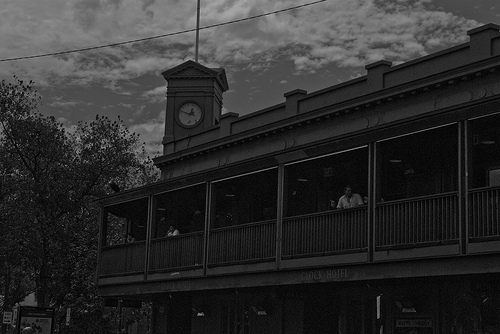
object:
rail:
[103, 240, 145, 250]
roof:
[150, 22, 500, 168]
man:
[336, 185, 364, 209]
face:
[346, 188, 353, 196]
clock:
[175, 98, 205, 128]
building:
[93, 22, 500, 334]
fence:
[147, 230, 203, 272]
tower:
[161, 59, 230, 155]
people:
[328, 186, 384, 210]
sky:
[0, 0, 500, 159]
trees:
[0, 70, 157, 334]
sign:
[18, 308, 51, 333]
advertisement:
[0, 310, 15, 327]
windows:
[102, 108, 500, 246]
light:
[196, 311, 203, 316]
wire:
[0, 0, 321, 63]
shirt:
[336, 194, 364, 209]